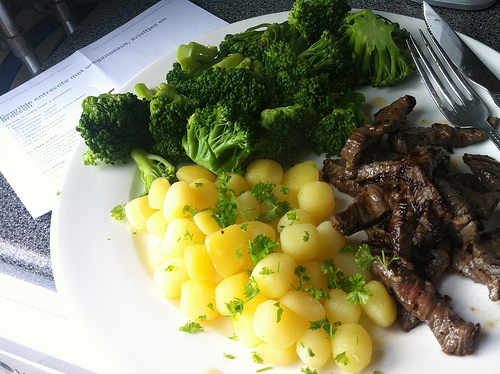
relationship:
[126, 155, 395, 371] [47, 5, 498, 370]
oregano chopped dish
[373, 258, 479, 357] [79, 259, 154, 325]
meat on plate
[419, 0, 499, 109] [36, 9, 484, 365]
knife on plate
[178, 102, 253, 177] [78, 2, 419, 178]
piece on broccoli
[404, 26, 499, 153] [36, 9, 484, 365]
fork on plate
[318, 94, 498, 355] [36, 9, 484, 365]
meat on plate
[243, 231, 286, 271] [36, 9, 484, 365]
herb on plate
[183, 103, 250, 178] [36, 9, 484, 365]
broccoli on a plate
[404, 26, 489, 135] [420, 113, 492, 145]
fork on meat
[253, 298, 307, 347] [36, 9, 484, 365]
potato on plate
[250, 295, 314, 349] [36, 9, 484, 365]
potato on plate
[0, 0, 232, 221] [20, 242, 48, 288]
paper on counter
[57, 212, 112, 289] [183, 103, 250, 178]
plate has broccoli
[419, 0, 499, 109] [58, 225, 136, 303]
knife on plate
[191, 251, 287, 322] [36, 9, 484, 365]
pasta on plate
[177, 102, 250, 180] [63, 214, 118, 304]
broccoli on plate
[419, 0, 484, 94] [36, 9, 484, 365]
knife on plate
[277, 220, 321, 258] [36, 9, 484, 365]
potato on plate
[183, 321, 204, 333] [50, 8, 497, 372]
leaf on plant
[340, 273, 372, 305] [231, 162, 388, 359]
parsley on boiled potatoes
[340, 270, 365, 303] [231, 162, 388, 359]
parsley on boiled potatoes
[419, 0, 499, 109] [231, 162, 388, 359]
knife on boiled potatoes